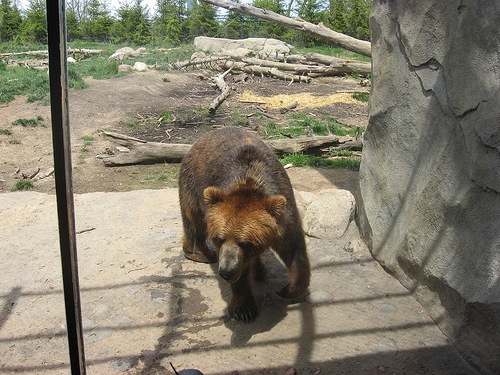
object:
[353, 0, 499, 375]
rock wall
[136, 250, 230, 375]
water stain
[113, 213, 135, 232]
ground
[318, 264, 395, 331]
shadow lines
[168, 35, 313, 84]
pile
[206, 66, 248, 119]
logs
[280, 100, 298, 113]
straw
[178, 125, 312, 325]
bear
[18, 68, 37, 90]
grass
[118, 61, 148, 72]
rocks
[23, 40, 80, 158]
window pane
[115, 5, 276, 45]
trees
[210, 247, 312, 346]
shadow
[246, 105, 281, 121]
branches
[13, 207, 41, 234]
part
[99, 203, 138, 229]
floor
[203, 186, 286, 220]
ears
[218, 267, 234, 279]
nose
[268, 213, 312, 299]
front leg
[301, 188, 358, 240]
rock